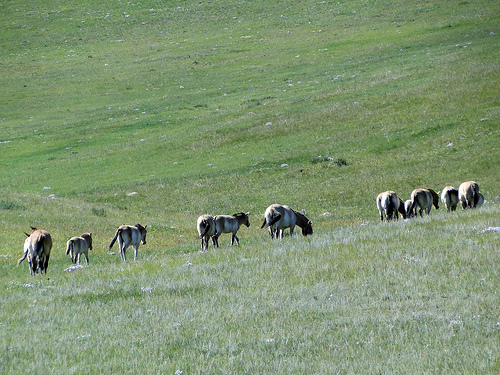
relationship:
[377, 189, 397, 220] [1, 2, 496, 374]
horse standing on grass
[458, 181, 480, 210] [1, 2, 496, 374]
animal standing on grass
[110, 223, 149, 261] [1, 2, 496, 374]
animal standing on grass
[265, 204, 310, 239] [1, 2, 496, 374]
horse standing on grass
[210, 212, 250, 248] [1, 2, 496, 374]
animal standing on grass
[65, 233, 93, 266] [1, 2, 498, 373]
animals grazing in field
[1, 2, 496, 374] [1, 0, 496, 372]
grass covering ground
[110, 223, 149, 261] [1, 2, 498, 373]
animal in field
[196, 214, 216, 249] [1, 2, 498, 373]
animal in field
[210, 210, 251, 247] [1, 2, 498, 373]
animal in field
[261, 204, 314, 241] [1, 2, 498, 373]
animal in field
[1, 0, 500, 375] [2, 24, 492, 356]
grass in field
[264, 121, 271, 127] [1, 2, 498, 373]
rock in field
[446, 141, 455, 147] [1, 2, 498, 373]
rock in field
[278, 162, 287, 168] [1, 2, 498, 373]
rock in field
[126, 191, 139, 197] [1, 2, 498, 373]
rock in field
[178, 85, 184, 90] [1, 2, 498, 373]
rock in field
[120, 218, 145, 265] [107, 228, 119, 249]
animal has tail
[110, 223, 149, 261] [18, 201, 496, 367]
animal grazing in field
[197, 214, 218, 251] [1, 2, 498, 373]
animal grazing in field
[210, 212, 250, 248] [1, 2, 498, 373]
animal grazing in field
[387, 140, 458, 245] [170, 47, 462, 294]
horse grazing field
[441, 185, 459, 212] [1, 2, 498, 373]
animal grazing in field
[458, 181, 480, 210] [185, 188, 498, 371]
animal grazing in field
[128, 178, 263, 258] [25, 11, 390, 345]
horse on hill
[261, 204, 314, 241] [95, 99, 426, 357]
animal eating grass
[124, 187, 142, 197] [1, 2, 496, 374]
rock in grass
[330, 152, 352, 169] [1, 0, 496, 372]
grass clump on ground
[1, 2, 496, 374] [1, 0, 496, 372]
grass on ground